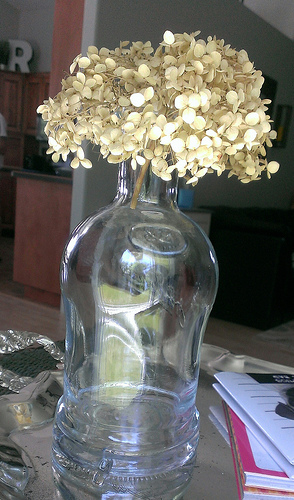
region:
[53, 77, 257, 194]
the flowers are white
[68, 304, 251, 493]
the vase of made of glass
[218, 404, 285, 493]
the books have pink covers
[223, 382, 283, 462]
stacked white papers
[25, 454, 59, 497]
the table is dirty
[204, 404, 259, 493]
paper is underneath the book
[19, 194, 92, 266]
the cabinets are brown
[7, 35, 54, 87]
an R is on top of the cabinet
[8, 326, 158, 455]
foil is on the table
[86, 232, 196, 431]
the vase is clear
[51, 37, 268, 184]
flowers in the pot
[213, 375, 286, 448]
paper on the table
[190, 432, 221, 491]
spots on the table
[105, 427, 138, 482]
reflection on the vase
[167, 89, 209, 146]
the flowers are yellow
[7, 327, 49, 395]
foil on the table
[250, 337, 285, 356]
wood on the floor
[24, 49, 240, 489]
a plant put at the clear vase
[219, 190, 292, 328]
a part of black sofa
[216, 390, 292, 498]
a pink notebook put at the table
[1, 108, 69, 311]
the kitchen part of the house to be seen at the left side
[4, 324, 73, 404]
a used silver foil beside at the clear vase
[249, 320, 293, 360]
a part of the printed carpet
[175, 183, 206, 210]
a blue box of tissue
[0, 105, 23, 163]
a part of the arms of a man standing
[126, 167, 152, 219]
a small brown stem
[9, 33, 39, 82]
a letter R on the top of the cabinet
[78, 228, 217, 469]
flower vessel is on the table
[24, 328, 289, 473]
the table is disorganised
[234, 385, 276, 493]
books are aranged on the table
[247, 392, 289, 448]
papers are white in color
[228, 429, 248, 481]
the book cover is pink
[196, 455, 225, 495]
table is grey in color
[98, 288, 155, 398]
yello wgreen paper reflected thropugh the bottle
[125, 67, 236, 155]
flowers are grey in color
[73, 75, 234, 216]
flower in a colorles vessel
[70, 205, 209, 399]
a vase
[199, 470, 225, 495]
the counter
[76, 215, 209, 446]
a glass vase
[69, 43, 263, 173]
small flowers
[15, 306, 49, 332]
a floor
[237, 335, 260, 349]
the wooden floor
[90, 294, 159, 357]
reflection in the clear glass vase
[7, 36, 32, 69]
the letter R is white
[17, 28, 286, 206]
a light colored flower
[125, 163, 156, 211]
the stem of the flower inside the bottle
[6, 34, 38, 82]
the letter R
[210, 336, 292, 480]
a white notebook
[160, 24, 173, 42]
a light colored petal on the flower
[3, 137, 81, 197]
a counter top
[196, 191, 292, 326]
a black couch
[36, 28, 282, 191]
white bouquet of flowers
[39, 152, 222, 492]
clear glass vase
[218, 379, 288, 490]
pink book on desk near vase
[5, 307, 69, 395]
silver ribbon laying near vase